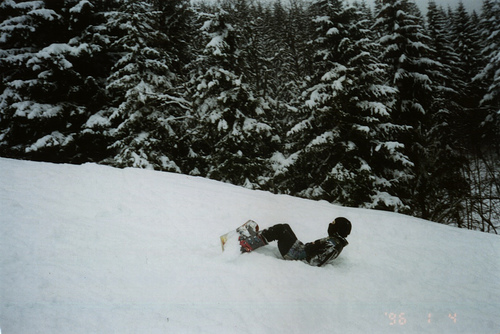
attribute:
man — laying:
[220, 215, 350, 264]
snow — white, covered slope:
[0, 158, 498, 332]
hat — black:
[329, 217, 351, 237]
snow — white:
[33, 179, 213, 318]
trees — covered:
[0, 0, 499, 238]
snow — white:
[389, 252, 440, 309]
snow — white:
[42, 211, 161, 290]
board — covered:
[207, 221, 252, 253]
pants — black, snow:
[267, 237, 317, 262]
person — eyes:
[277, 210, 397, 287]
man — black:
[236, 209, 352, 268]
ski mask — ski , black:
[327, 216, 352, 238]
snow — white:
[121, 245, 188, 284]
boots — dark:
[233, 220, 283, 268]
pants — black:
[238, 188, 299, 275]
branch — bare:
[458, 190, 496, 233]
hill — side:
[407, 190, 497, 306]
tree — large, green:
[277, 0, 417, 211]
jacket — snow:
[284, 230, 349, 265]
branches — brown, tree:
[471, 166, 498, 217]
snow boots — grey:
[242, 210, 258, 255]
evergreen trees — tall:
[25, 3, 415, 141]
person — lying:
[223, 203, 366, 267]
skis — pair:
[217, 215, 267, 250]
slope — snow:
[17, 146, 222, 318]